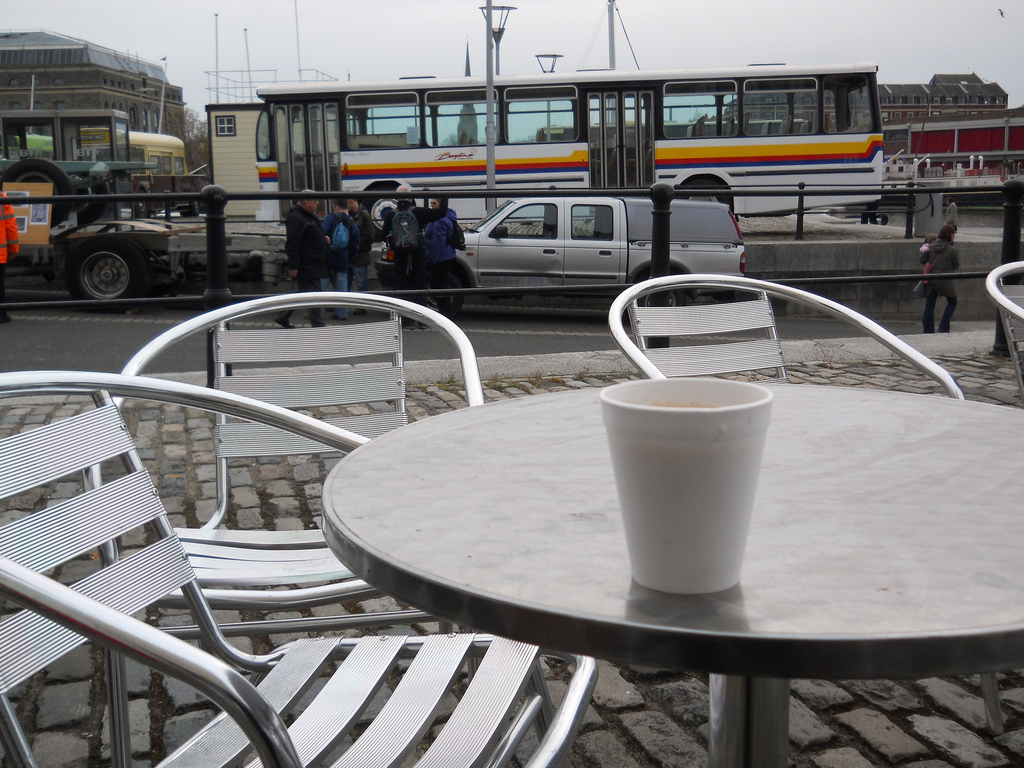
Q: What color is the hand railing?
A: Black.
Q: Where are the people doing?
A: Walking.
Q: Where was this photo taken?
A: At an outdoor cafe.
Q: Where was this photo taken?
A: At a restaurant.